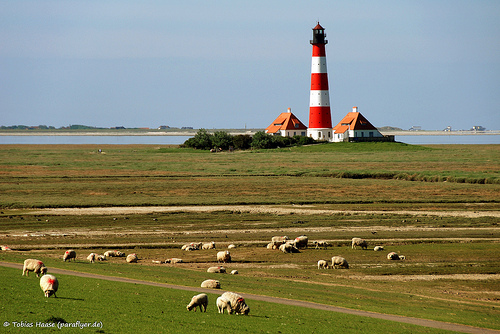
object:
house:
[264, 107, 307, 137]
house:
[332, 106, 384, 138]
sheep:
[200, 279, 221, 289]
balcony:
[309, 21, 328, 45]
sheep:
[293, 235, 308, 249]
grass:
[107, 294, 169, 313]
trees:
[184, 129, 215, 151]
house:
[332, 112, 378, 130]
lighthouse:
[306, 17, 334, 142]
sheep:
[39, 274, 59, 298]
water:
[8, 129, 498, 150]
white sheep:
[22, 258, 49, 278]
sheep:
[215, 291, 250, 316]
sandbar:
[0, 124, 491, 134]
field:
[0, 124, 498, 334]